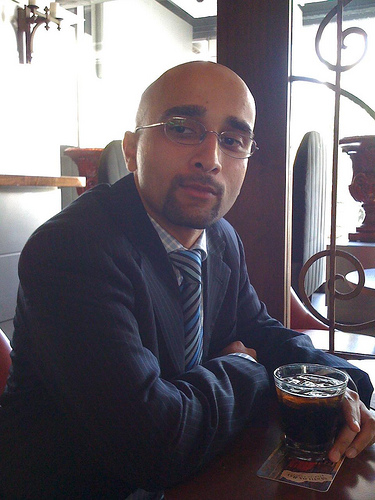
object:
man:
[8, 79, 308, 474]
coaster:
[267, 453, 324, 485]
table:
[193, 466, 259, 493]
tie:
[180, 271, 222, 339]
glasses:
[163, 112, 260, 160]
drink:
[265, 358, 374, 436]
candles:
[28, 7, 60, 33]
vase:
[67, 145, 106, 184]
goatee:
[170, 182, 223, 232]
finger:
[343, 396, 375, 436]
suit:
[63, 210, 190, 339]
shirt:
[163, 232, 176, 246]